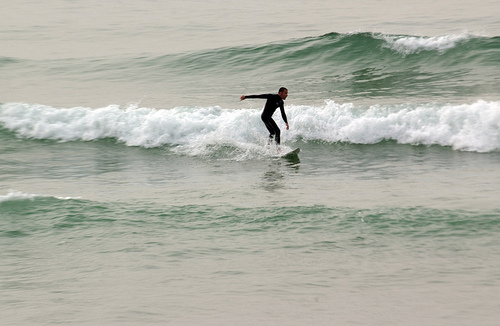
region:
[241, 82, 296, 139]
Surfer in black wetsuit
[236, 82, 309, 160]
Man on surfboard wearing wetsuit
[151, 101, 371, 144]
White foamy wave behind surfer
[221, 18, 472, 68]
Green wave about to crest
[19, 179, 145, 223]
Small wave rolling to shore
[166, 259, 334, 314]
Calm green ocean water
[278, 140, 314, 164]
Front of surfboard sticking out of water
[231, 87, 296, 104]
Man in wetsuit with arm outstretched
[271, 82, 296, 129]
Man in wetsuit with arm hanging down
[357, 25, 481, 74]
Large green wave with white top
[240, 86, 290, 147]
surfer wearing wetsuit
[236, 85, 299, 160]
surfer standing atop surf board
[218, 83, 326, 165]
surfer riding already broken wave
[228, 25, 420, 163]
surfer in front of large swell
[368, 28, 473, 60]
white cap on cresting wave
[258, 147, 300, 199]
reflection of surfer in water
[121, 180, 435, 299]
ocean water is green blue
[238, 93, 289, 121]
rash guard protects arms and torso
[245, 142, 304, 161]
surfboard sprays as it breaks water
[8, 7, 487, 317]
muted light suggests overcast sky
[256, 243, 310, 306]
part of a water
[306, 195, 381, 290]
part of some waves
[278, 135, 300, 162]
edge of a board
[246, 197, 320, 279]
edge of a wave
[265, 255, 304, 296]
part of a water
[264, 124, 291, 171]
part of a board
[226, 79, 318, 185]
man on a surfboard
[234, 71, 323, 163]
surfer on a surfboard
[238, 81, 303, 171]
man in a wetsuit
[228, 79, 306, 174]
surfer in a wet suit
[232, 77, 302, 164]
person on a surfboard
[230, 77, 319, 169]
person in a wetsuit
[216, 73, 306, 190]
person with extended left arm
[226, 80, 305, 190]
man with extended left arm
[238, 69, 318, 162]
surfer with extended left arm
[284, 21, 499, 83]
wave behind the surfer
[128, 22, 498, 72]
the biggest ocean wave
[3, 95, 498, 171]
this is the broken wave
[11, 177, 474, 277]
this is a ripple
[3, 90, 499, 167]
this is ocean foam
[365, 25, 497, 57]
this is white spray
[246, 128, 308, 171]
this is a surfboard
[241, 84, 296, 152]
this is a wetsuit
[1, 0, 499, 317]
this is the water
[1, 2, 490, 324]
this is the ocean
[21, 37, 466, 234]
these are ocean waves